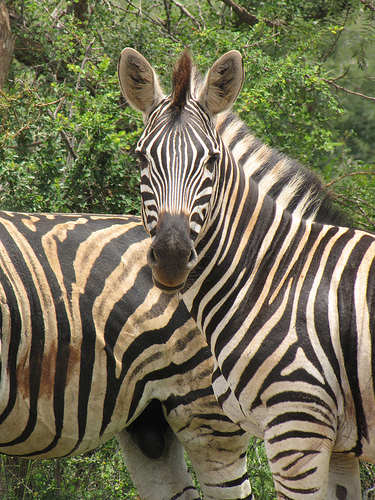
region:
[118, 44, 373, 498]
A zebra staring at the camera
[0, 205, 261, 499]
A zebra covered in dirt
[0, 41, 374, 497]
A pair of zebras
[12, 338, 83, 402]
A spot of mud on a zebra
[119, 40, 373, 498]
a black and white zebra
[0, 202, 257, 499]
a black and white zebra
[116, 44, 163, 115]
The left ear of the zebra.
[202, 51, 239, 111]
The right ear of the zebra.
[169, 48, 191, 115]
The mane on the zebra's head.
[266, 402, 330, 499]
The front right leg of the zebra.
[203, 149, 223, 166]
The right eye of the zebra.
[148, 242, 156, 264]
The left nostril of the zebra's nose.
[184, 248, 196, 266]
The right nostril of the zebra's nose.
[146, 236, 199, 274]
The nose of the zebra.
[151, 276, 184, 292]
The mouth of the zebra.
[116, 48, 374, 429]
black and brown striped zebra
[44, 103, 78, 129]
green leaves in brown tree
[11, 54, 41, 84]
green leaves in brown tree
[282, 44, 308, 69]
green leaves in brown tree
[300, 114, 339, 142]
green leaves in brown tree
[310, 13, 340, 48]
green leaves in brown tree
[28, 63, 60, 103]
green leaves in brown tree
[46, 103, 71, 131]
green leaves in brown tree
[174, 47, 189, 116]
Mohawk shaped mane on a zebra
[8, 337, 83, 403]
Mud spot on a zebra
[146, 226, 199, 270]
Black nose on a zebra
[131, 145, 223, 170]
Eyes in a zebra's head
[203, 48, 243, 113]
Ear on a zebra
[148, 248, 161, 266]
Nostril on a zebra's nose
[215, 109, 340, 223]
Black and white striped mane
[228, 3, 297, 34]
Tree branch behind zebras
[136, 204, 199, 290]
the nose is black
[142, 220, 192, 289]
the nose is black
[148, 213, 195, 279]
the nose is black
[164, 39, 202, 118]
the mane of a zebra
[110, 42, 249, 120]
the ear of zebra is long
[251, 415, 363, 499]
front legs of zebra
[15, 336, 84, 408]
brown stain on zebra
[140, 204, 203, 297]
muzzle of zebra is black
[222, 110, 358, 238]
mane of zebra on the neck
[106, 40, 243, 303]
head of a zebra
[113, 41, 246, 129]
ears of a zebra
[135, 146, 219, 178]
eyes of a zebra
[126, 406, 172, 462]
testicles of a zebra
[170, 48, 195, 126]
mane of the zebra's head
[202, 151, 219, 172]
eyeball of the zebra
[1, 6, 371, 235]
green vegatation behind zebra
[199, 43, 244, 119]
the zebra's left ear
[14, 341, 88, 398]
brown spot on zebra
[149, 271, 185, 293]
mouth of zebra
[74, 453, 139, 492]
a view of trees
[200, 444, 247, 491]
a view of legs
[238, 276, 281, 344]
a view of skin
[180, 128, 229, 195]
a view of eyes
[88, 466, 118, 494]
a view of trees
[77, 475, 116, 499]
a view of leaves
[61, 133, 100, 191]
a view of stems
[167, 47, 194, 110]
The red mohawk on the zebra.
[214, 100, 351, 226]
The hair on the zebras back.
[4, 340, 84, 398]
The brown patch on the zebra.